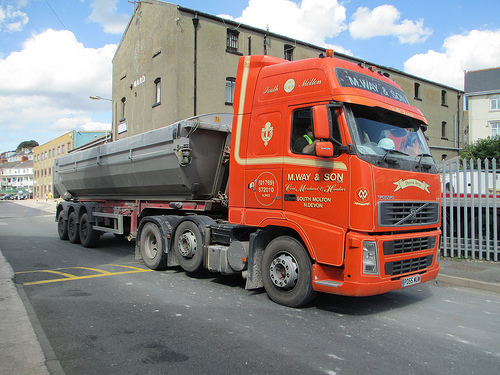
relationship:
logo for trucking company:
[390, 172, 434, 198] [285, 171, 352, 190]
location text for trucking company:
[281, 183, 348, 210] [285, 171, 352, 190]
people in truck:
[298, 119, 313, 150] [42, 45, 463, 314]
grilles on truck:
[377, 199, 438, 275] [42, 45, 463, 314]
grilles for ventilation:
[377, 199, 438, 275] [377, 199, 444, 231]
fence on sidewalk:
[457, 151, 494, 266] [461, 260, 496, 289]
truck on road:
[42, 45, 463, 314] [0, 200, 500, 375]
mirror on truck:
[305, 100, 340, 163] [42, 45, 463, 314]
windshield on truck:
[347, 105, 436, 166] [42, 45, 463, 314]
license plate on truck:
[400, 273, 423, 292] [42, 45, 463, 314]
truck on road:
[42, 45, 463, 314] [383, 309, 455, 355]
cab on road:
[220, 48, 458, 257] [383, 309, 455, 355]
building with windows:
[98, 4, 214, 106] [150, 75, 165, 107]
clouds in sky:
[5, 22, 102, 94] [440, 6, 473, 25]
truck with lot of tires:
[42, 45, 463, 314] [140, 222, 194, 271]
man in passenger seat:
[298, 119, 313, 150] [296, 118, 304, 134]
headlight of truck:
[356, 235, 380, 276] [42, 45, 463, 314]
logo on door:
[390, 172, 434, 198] [278, 154, 342, 213]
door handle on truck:
[272, 181, 309, 209] [42, 45, 463, 314]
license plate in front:
[400, 273, 423, 292] [372, 234, 442, 289]